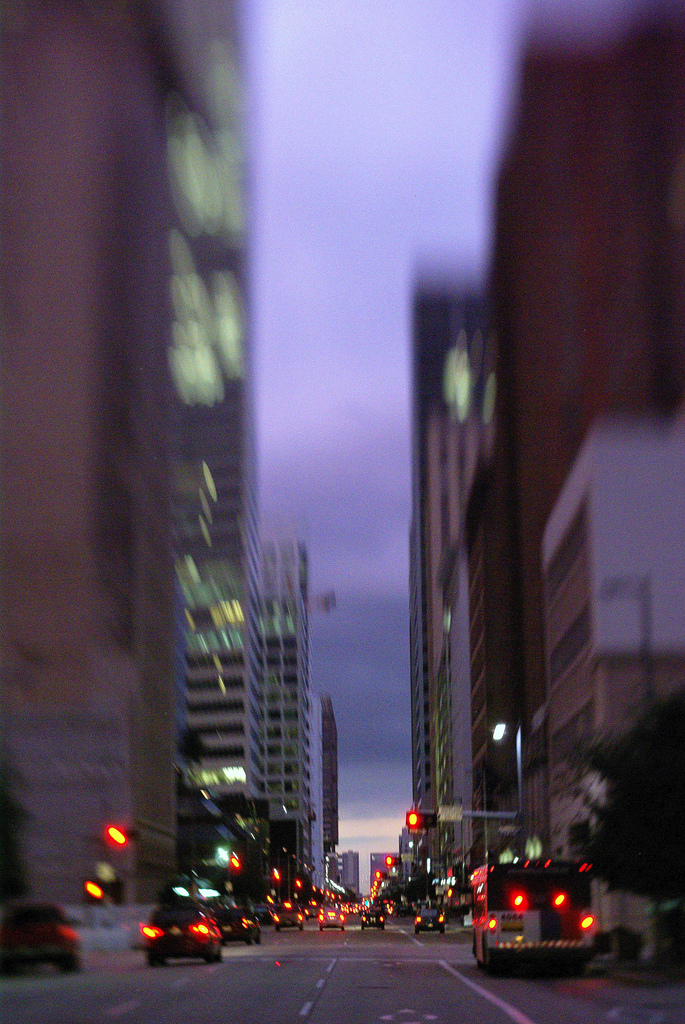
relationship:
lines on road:
[236, 942, 380, 1009] [9, 868, 665, 1009]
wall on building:
[59, 111, 221, 422] [59, 111, 221, 824]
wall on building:
[24, 33, 375, 678] [24, 33, 375, 678]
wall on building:
[241, 621, 333, 793] [241, 621, 333, 793]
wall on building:
[507, 234, 681, 472] [382, 234, 681, 935]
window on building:
[236, 759, 283, 788] [236, 504, 283, 788]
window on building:
[249, 715, 301, 781] [213, 516, 301, 782]